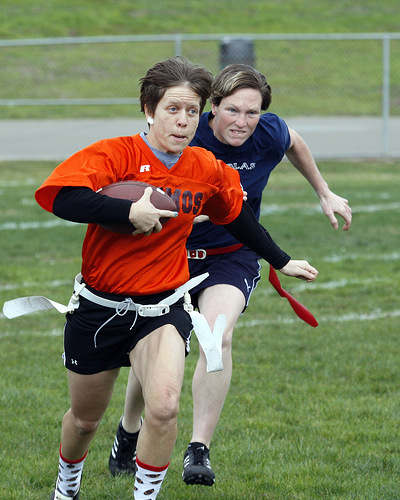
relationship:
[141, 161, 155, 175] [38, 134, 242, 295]
letter on shirt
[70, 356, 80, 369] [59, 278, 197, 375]
emblem on shorts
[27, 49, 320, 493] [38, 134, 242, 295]
player in shirt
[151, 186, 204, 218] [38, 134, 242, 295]
letters on shirt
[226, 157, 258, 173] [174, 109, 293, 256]
letters on shirt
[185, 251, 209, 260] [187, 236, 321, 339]
belt fastener on belt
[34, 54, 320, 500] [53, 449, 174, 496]
player wearing socks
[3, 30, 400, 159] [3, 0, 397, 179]
fence in background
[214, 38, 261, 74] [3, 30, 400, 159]
garbage can behind fence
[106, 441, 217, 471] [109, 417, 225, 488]
stripes on cleats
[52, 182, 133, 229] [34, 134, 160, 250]
sleeve on arm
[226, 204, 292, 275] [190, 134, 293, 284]
sleeve on arm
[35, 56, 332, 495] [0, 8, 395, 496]
person on grass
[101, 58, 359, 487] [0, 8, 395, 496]
person on grass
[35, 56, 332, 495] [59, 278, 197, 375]
person wearing shorts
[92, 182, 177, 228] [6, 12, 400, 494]
football in photo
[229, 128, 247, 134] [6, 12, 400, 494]
teeth in photo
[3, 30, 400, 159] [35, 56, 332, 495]
fence behind person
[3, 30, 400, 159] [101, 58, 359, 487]
fence behind person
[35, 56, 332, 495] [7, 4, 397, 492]
person playing football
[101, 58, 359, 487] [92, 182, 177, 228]
person playing football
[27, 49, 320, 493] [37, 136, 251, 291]
player in orange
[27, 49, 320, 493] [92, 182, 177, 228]
player has ball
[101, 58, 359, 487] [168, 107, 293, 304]
person in blue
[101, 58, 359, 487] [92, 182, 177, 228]
person pursuing ball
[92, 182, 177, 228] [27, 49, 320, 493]
football carried by player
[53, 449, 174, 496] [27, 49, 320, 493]
socks worn by player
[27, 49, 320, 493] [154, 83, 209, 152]
player has face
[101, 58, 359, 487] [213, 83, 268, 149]
person has face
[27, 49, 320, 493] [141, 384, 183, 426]
player has knee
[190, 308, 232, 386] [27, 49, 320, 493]
flag attached to player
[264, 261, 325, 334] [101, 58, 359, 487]
flag attached to person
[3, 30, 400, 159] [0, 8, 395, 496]
fence next to grass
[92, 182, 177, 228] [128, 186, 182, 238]
football in hand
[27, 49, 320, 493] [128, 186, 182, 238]
player has hand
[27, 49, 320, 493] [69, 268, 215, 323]
player has belt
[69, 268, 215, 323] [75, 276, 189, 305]
belt around waist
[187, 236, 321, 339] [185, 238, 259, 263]
belt around waist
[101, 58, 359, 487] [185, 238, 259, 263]
person has waist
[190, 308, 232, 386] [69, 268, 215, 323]
flag on belt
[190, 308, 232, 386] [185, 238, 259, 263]
flag on waist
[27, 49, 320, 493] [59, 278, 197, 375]
player wearing shorts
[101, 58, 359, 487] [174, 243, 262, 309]
person wearing shorts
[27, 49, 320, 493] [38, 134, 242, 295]
player wearing shirt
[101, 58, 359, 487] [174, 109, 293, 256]
person wearing shirt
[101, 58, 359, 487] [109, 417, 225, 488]
person wearing cleats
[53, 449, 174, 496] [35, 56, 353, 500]
socks on person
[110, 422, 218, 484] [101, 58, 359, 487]
shoes on person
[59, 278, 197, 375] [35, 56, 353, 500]
shorts on person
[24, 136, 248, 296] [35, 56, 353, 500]
jersey on person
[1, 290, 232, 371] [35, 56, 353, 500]
flags on person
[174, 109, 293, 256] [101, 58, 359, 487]
shirt on person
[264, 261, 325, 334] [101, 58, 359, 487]
flag on person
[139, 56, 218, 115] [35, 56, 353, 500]
hair on person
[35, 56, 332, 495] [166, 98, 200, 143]
person with grimace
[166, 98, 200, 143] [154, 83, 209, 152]
grimace on face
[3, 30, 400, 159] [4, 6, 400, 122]
fence by field